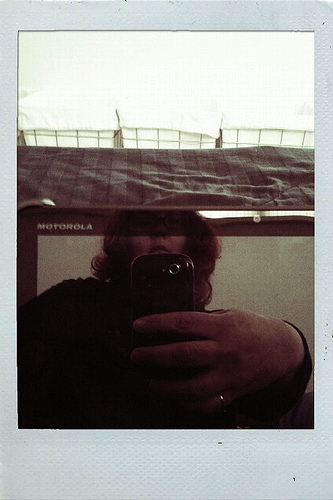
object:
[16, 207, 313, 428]
woman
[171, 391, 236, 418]
finger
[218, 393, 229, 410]
ring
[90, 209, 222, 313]
hair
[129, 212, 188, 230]
glasses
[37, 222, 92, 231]
label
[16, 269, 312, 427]
shirt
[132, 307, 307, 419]
hand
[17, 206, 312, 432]
reflection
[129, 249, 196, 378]
cellphone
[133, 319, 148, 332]
finger nail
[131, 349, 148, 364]
finger nail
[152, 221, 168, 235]
nose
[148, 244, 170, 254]
mouth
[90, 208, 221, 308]
head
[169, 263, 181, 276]
camera lens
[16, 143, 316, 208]
awning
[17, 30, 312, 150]
sky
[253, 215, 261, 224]
camera spot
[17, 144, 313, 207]
drapes